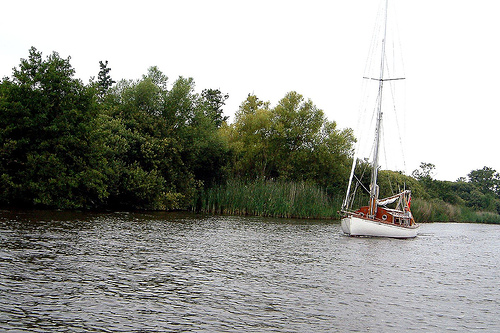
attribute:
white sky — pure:
[46, 4, 362, 47]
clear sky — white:
[1, 4, 498, 186]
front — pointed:
[338, 209, 378, 244]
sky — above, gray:
[209, 31, 367, 77]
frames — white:
[361, 205, 402, 222]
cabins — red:
[354, 200, 414, 236]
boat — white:
[308, 0, 435, 242]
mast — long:
[349, 0, 412, 204]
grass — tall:
[191, 167, 333, 233]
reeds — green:
[192, 170, 499, 222]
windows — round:
[356, 211, 390, 224]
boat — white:
[336, 0, 420, 238]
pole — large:
[369, 1, 384, 211]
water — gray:
[90, 218, 326, 301]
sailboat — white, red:
[334, 17, 421, 248]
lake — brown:
[60, 246, 375, 313]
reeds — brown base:
[210, 187, 289, 221]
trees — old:
[0, 47, 357, 216]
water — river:
[0, 213, 498, 330]